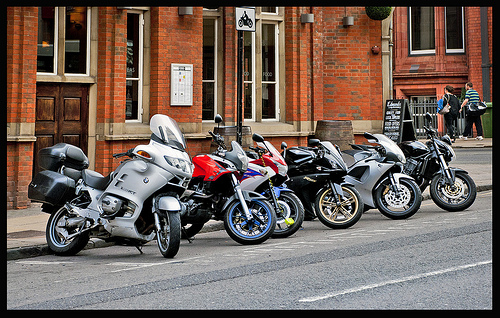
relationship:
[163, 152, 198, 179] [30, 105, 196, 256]
light on motorcycle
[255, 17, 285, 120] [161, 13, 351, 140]
window on building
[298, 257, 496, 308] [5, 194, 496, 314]
line on street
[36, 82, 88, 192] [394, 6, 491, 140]
door to a building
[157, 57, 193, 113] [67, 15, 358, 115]
sign on building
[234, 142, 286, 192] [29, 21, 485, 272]
light on building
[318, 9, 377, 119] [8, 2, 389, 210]
brick on building